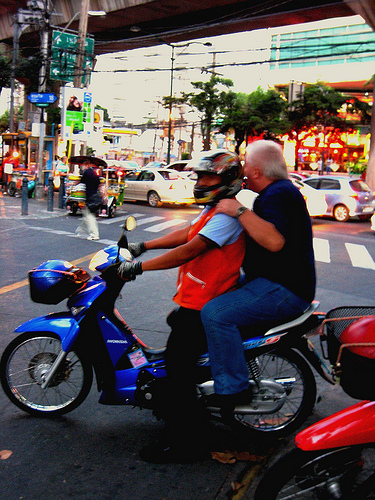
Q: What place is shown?
A: It is a street.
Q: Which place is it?
A: It is a street.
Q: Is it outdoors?
A: Yes, it is outdoors.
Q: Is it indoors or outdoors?
A: It is outdoors.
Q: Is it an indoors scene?
A: No, it is outdoors.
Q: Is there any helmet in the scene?
A: Yes, there is a helmet.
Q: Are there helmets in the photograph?
A: Yes, there is a helmet.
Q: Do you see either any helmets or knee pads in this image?
A: Yes, there is a helmet.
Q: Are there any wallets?
A: No, there are no wallets.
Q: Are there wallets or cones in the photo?
A: No, there are no wallets or cones.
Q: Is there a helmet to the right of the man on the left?
A: Yes, there is a helmet to the right of the man.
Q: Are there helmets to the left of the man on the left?
A: No, the helmet is to the right of the man.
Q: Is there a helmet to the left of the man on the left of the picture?
A: No, the helmet is to the right of the man.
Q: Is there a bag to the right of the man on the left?
A: No, there is a helmet to the right of the man.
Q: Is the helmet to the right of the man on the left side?
A: Yes, the helmet is to the right of the man.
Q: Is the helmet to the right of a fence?
A: No, the helmet is to the right of the man.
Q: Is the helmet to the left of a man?
A: No, the helmet is to the right of a man.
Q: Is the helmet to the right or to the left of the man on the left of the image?
A: The helmet is to the right of the man.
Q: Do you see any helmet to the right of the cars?
A: Yes, there is a helmet to the right of the cars.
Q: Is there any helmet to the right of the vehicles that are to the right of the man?
A: Yes, there is a helmet to the right of the cars.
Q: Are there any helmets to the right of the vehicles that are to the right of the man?
A: Yes, there is a helmet to the right of the cars.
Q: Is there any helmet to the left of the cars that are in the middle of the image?
A: No, the helmet is to the right of the cars.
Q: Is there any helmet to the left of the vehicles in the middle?
A: No, the helmet is to the right of the cars.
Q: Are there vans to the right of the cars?
A: No, there is a helmet to the right of the cars.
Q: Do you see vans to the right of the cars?
A: No, there is a helmet to the right of the cars.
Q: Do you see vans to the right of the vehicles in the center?
A: No, there is a helmet to the right of the cars.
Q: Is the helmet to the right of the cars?
A: Yes, the helmet is to the right of the cars.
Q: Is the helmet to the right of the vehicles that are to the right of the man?
A: Yes, the helmet is to the right of the cars.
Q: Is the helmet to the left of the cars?
A: No, the helmet is to the right of the cars.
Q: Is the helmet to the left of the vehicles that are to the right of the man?
A: No, the helmet is to the right of the cars.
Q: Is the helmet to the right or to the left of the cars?
A: The helmet is to the right of the cars.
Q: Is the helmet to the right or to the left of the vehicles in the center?
A: The helmet is to the right of the cars.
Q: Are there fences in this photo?
A: No, there are no fences.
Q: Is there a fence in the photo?
A: No, there are no fences.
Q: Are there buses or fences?
A: No, there are no fences or buses.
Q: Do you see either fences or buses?
A: No, there are no fences or buses.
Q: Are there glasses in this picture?
A: No, there are no glasses.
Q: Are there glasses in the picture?
A: No, there are no glasses.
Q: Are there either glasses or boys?
A: No, there are no glasses or boys.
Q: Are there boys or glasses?
A: No, there are no glasses or boys.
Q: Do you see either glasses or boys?
A: No, there are no glasses or boys.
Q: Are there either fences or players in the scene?
A: No, there are no fences or players.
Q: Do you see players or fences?
A: No, there are no fences or players.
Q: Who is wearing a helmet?
A: The man is wearing a helmet.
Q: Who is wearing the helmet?
A: The man is wearing a helmet.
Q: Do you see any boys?
A: No, there are no boys.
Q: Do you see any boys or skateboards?
A: No, there are no boys or skateboards.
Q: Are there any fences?
A: No, there are no fences.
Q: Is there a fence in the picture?
A: No, there are no fences.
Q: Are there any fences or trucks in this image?
A: No, there are no fences or trucks.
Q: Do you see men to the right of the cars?
A: Yes, there is a man to the right of the cars.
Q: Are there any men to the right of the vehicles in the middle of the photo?
A: Yes, there is a man to the right of the cars.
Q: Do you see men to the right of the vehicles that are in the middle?
A: Yes, there is a man to the right of the cars.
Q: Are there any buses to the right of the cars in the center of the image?
A: No, there is a man to the right of the cars.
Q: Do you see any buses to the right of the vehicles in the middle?
A: No, there is a man to the right of the cars.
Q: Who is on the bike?
A: The man is on the bike.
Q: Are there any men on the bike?
A: Yes, there is a man on the bike.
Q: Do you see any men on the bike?
A: Yes, there is a man on the bike.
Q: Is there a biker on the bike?
A: No, there is a man on the bike.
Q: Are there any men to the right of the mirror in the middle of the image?
A: Yes, there is a man to the right of the mirror.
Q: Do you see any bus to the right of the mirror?
A: No, there is a man to the right of the mirror.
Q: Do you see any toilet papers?
A: No, there are no toilet papers.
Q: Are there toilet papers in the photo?
A: No, there are no toilet papers.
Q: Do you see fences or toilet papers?
A: No, there are no toilet papers or fences.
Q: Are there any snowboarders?
A: No, there are no snowboarders.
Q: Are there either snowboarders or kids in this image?
A: No, there are no snowboarders or kids.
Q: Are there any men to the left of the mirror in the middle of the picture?
A: Yes, there is a man to the left of the mirror.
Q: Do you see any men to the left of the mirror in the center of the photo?
A: Yes, there is a man to the left of the mirror.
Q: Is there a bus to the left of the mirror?
A: No, there is a man to the left of the mirror.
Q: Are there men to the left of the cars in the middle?
A: Yes, there is a man to the left of the cars.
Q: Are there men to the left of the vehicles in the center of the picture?
A: Yes, there is a man to the left of the cars.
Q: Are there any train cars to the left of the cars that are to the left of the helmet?
A: No, there is a man to the left of the cars.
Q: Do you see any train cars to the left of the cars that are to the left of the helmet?
A: No, there is a man to the left of the cars.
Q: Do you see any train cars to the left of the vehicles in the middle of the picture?
A: No, there is a man to the left of the cars.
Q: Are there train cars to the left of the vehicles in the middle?
A: No, there is a man to the left of the cars.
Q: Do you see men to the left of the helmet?
A: Yes, there is a man to the left of the helmet.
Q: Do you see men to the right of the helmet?
A: No, the man is to the left of the helmet.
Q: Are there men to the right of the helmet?
A: No, the man is to the left of the helmet.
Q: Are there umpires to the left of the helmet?
A: No, there is a man to the left of the helmet.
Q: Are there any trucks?
A: No, there are no trucks.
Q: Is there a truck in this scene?
A: No, there are no trucks.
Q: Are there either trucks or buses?
A: No, there are no trucks or buses.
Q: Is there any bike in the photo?
A: Yes, there is a bike.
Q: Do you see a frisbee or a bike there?
A: Yes, there is a bike.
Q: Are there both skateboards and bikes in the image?
A: No, there is a bike but no skateboards.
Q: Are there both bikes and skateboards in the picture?
A: No, there is a bike but no skateboards.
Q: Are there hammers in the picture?
A: No, there are no hammers.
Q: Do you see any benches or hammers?
A: No, there are no hammers or benches.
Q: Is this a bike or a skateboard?
A: This is a bike.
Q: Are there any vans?
A: No, there are no vans.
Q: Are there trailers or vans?
A: No, there are no vans or trailers.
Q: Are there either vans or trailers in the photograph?
A: No, there are no vans or trailers.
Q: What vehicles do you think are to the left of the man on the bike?
A: The vehicles are cars.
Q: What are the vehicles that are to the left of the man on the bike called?
A: The vehicles are cars.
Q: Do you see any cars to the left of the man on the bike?
A: Yes, there are cars to the left of the man.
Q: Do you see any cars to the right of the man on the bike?
A: No, the cars are to the left of the man.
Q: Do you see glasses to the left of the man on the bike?
A: No, there are cars to the left of the man.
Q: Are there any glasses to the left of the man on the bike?
A: No, there are cars to the left of the man.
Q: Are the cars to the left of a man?
A: Yes, the cars are to the left of a man.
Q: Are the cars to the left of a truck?
A: No, the cars are to the left of a man.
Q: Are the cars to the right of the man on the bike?
A: No, the cars are to the left of the man.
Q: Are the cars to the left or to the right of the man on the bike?
A: The cars are to the left of the man.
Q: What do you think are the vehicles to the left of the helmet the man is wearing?
A: The vehicles are cars.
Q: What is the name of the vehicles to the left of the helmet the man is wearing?
A: The vehicles are cars.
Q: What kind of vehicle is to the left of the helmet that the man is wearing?
A: The vehicles are cars.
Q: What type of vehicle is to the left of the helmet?
A: The vehicles are cars.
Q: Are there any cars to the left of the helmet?
A: Yes, there are cars to the left of the helmet.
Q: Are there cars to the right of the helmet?
A: No, the cars are to the left of the helmet.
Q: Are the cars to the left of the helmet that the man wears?
A: Yes, the cars are to the left of the helmet.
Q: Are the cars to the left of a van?
A: No, the cars are to the left of the helmet.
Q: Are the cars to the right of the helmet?
A: No, the cars are to the left of the helmet.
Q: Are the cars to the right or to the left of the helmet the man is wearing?
A: The cars are to the left of the helmet.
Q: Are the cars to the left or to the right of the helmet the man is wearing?
A: The cars are to the left of the helmet.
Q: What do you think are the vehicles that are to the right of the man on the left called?
A: The vehicles are cars.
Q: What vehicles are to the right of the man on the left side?
A: The vehicles are cars.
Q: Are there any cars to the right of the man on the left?
A: Yes, there are cars to the right of the man.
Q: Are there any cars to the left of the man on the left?
A: No, the cars are to the right of the man.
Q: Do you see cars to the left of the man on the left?
A: No, the cars are to the right of the man.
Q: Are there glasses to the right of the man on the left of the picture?
A: No, there are cars to the right of the man.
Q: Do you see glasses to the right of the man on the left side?
A: No, there are cars to the right of the man.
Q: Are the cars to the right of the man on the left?
A: Yes, the cars are to the right of the man.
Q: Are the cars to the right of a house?
A: No, the cars are to the right of the man.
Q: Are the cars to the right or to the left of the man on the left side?
A: The cars are to the right of the man.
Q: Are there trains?
A: No, there are no trains.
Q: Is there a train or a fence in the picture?
A: No, there are no trains or fences.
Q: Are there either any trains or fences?
A: No, there are no trains or fences.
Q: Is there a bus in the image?
A: No, there are no buses.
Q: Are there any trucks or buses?
A: No, there are no buses or trucks.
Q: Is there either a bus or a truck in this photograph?
A: No, there are no buses or trucks.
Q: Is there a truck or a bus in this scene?
A: No, there are no buses or trucks.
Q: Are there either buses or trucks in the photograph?
A: No, there are no buses or trucks.